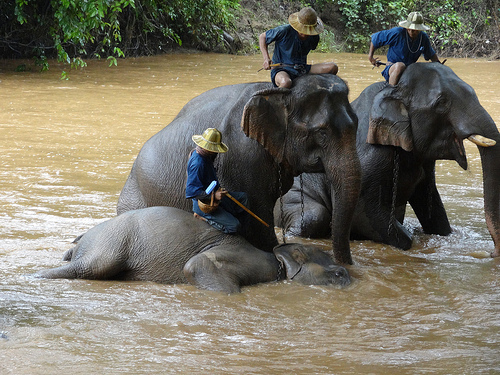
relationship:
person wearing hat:
[368, 12, 442, 86] [397, 11, 430, 32]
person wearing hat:
[258, 6, 338, 88] [286, 7, 323, 36]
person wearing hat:
[185, 127, 250, 233] [190, 127, 228, 155]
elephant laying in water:
[38, 204, 354, 294] [1, 51, 499, 374]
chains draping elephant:
[386, 145, 436, 242] [274, 62, 499, 258]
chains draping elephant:
[276, 163, 307, 244] [117, 73, 362, 265]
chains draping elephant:
[275, 260, 284, 282] [38, 204, 354, 294]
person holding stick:
[185, 127, 250, 233] [220, 187, 272, 228]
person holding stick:
[258, 6, 338, 88] [257, 62, 282, 73]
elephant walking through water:
[274, 62, 499, 258] [1, 51, 499, 374]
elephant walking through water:
[117, 73, 362, 265] [1, 51, 499, 374]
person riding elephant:
[368, 12, 442, 86] [274, 62, 499, 258]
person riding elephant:
[258, 6, 338, 88] [117, 73, 362, 265]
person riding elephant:
[185, 127, 250, 233] [38, 204, 354, 294]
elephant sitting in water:
[274, 62, 499, 258] [1, 51, 499, 374]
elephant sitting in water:
[117, 73, 362, 265] [1, 51, 499, 374]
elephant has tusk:
[274, 62, 499, 258] [468, 133, 496, 148]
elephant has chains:
[38, 204, 354, 294] [275, 260, 284, 282]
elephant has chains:
[274, 62, 499, 258] [386, 145, 436, 242]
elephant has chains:
[117, 73, 362, 265] [276, 163, 307, 244]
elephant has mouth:
[274, 62, 499, 258] [450, 129, 480, 171]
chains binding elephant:
[386, 145, 436, 242] [274, 62, 499, 258]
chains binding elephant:
[276, 163, 307, 244] [117, 73, 362, 265]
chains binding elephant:
[275, 260, 284, 282] [38, 204, 354, 294]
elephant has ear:
[38, 204, 354, 294] [273, 242, 309, 280]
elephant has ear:
[274, 62, 499, 258] [366, 86, 413, 152]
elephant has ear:
[117, 73, 362, 265] [239, 89, 289, 165]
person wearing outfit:
[368, 12, 442, 86] [372, 28, 436, 81]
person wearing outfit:
[258, 6, 338, 88] [265, 24, 319, 87]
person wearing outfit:
[185, 127, 250, 233] [185, 152, 249, 233]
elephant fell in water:
[38, 204, 354, 294] [1, 51, 499, 374]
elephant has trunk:
[274, 62, 499, 258] [472, 107, 498, 258]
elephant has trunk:
[117, 73, 362, 265] [319, 152, 361, 265]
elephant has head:
[38, 204, 354, 294] [273, 242, 352, 289]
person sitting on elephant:
[368, 12, 442, 86] [274, 62, 499, 258]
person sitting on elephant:
[258, 6, 338, 88] [117, 73, 362, 265]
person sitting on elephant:
[185, 127, 250, 233] [38, 204, 354, 294]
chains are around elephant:
[386, 145, 436, 242] [274, 62, 499, 258]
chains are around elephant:
[276, 163, 307, 244] [117, 73, 362, 265]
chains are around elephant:
[275, 260, 284, 282] [38, 204, 354, 294]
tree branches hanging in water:
[1, 1, 242, 82] [1, 51, 499, 374]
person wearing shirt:
[368, 12, 442, 86] [372, 27, 435, 65]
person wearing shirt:
[258, 6, 338, 88] [264, 27, 318, 67]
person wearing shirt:
[185, 127, 250, 233] [185, 152, 221, 201]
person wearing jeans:
[185, 127, 250, 233] [192, 191, 249, 235]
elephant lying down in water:
[38, 204, 354, 294] [1, 51, 499, 374]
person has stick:
[185, 127, 250, 233] [220, 187, 272, 228]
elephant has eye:
[274, 62, 499, 258] [437, 97, 449, 108]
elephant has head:
[117, 73, 362, 265] [242, 72, 363, 264]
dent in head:
[294, 90, 331, 130] [242, 72, 363, 264]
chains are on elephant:
[386, 145, 436, 242] [274, 62, 499, 258]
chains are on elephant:
[276, 163, 307, 244] [117, 73, 362, 265]